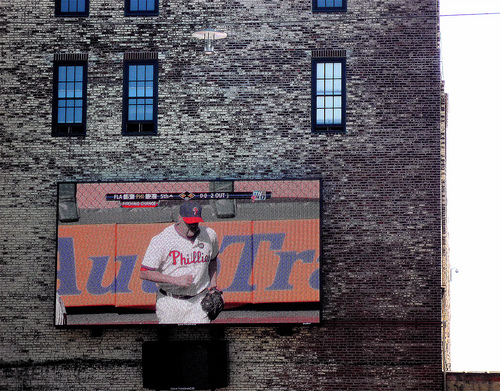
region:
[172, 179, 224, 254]
the head of a man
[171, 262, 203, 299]
the hand of a man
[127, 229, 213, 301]
the arm of a man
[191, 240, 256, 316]
a man wearing a glove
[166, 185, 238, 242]
a man wearing a blue and red hat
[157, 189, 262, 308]
a man wearing a uniform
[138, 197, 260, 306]
a man wearing a white shirt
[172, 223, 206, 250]
the chin of a man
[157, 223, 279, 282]
a man with letters on his shirt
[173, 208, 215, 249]
the face of a man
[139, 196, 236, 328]
baseball player on screen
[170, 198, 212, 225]
baseball player wearing hat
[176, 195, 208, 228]
players hat is blue and red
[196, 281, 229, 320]
player is wearing glove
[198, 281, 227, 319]
players glove is black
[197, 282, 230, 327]
players glove is on left hand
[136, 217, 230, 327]
players jersey is white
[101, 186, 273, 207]
scoreboard at top of screen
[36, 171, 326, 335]
large screen on wall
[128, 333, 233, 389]
small black screen on wall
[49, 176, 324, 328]
television screen showing baseball player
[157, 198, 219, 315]
baseball player for the Phillies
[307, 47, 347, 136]
window on a brick building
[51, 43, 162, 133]
sky reflected in glass window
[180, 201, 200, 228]
blue and red baseball cap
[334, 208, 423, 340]
brick wall of a building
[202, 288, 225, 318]
black glove worn by a baseball player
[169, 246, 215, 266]
Phillies team name on baseball player shirt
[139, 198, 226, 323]
Baseball player shown on television screen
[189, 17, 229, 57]
hanging lamp light is on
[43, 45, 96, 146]
black framed reflective blue windows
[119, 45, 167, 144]
black framed reflective blue windows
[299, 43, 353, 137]
black framed reflective blue windows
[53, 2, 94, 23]
black framed reflective blue windows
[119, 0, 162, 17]
black framed reflective blue windows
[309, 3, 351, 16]
black framed reflective blue windows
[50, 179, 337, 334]
large television screen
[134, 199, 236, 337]
phillies base ball player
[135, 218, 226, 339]
white base ball uniform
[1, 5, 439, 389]
black brick building